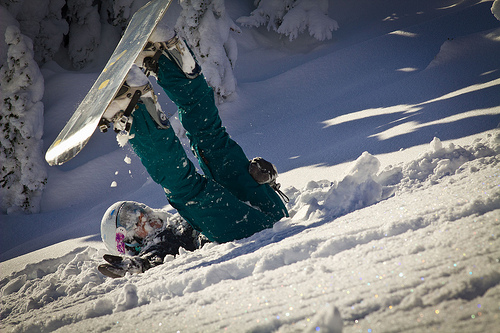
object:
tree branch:
[35, 10, 69, 52]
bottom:
[45, 0, 171, 167]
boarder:
[96, 4, 290, 277]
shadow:
[176, 174, 391, 275]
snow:
[0, 0, 500, 333]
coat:
[138, 217, 214, 273]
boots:
[95, 81, 153, 134]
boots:
[137, 29, 187, 80]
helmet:
[100, 200, 166, 256]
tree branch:
[0, 29, 55, 218]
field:
[0, 145, 500, 333]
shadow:
[261, 55, 500, 169]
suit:
[127, 51, 290, 267]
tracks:
[0, 195, 500, 333]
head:
[100, 200, 163, 258]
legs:
[124, 69, 281, 243]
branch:
[175, 0, 243, 104]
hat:
[100, 199, 163, 255]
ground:
[3, 30, 498, 328]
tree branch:
[233, 0, 346, 44]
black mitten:
[97, 253, 152, 278]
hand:
[97, 253, 149, 279]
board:
[44, 0, 172, 168]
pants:
[125, 61, 288, 245]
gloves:
[97, 157, 290, 279]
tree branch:
[172, 0, 244, 106]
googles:
[100, 194, 157, 247]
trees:
[0, 0, 500, 216]